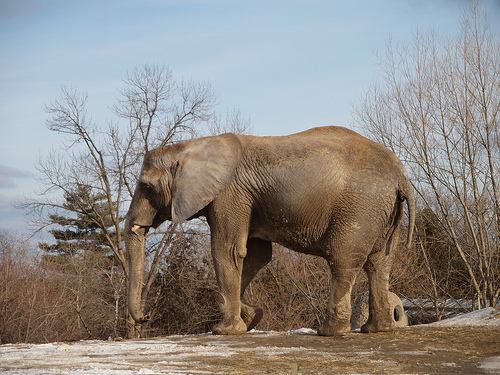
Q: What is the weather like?
A: It is cloudless.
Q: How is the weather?
A: It is cloudless.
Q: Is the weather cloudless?
A: Yes, it is cloudless.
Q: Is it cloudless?
A: Yes, it is cloudless.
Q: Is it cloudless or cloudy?
A: It is cloudless.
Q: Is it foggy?
A: No, it is cloudless.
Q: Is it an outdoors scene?
A: Yes, it is outdoors.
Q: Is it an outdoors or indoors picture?
A: It is outdoors.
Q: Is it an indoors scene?
A: No, it is outdoors.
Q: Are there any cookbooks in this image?
A: No, there are no cookbooks.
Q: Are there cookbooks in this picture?
A: No, there are no cookbooks.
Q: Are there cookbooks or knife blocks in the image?
A: No, there are no cookbooks or knife blocks.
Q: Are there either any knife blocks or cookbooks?
A: No, there are no cookbooks or knife blocks.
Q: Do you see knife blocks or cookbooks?
A: No, there are no cookbooks or knife blocks.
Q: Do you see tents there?
A: No, there are no tents.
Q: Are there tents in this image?
A: No, there are no tents.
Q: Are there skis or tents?
A: No, there are no tents or skis.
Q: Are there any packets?
A: No, there are no packets.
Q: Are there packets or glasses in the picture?
A: No, there are no packets or glasses.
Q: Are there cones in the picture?
A: No, there are no cones.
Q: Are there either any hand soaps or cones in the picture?
A: No, there are no cones or hand soaps.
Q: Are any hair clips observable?
A: No, there are no hair clips.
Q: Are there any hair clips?
A: No, there are no hair clips.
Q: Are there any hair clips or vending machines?
A: No, there are no hair clips or vending machines.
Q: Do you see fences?
A: No, there are no fences.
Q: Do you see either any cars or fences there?
A: No, there are no fences or cars.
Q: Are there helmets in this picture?
A: No, there are no helmets.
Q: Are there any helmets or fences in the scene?
A: No, there are no helmets or fences.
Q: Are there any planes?
A: No, there are no planes.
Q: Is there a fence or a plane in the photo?
A: No, there are no airplanes or fences.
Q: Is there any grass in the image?
A: Yes, there is grass.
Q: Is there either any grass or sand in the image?
A: Yes, there is grass.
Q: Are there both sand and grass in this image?
A: No, there is grass but no sand.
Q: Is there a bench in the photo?
A: No, there are no benches.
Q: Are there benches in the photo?
A: No, there are no benches.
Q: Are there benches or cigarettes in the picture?
A: No, there are no benches or cigarettes.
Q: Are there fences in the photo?
A: No, there are no fences.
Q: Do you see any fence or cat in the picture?
A: No, there are no fences or cats.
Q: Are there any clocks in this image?
A: No, there are no clocks.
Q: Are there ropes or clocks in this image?
A: No, there are no clocks or ropes.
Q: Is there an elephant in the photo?
A: Yes, there is an elephant.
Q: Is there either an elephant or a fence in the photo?
A: Yes, there is an elephant.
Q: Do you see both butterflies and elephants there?
A: No, there is an elephant but no butterflies.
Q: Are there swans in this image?
A: No, there are no swans.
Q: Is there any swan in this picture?
A: No, there are no swans.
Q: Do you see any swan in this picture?
A: No, there are no swans.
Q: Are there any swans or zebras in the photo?
A: No, there are no swans or zebras.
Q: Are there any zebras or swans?
A: No, there are no swans or zebras.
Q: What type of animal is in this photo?
A: The animal is an elephant.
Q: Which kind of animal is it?
A: The animal is an elephant.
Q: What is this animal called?
A: This is an elephant.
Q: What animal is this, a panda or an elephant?
A: This is an elephant.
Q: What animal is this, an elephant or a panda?
A: This is an elephant.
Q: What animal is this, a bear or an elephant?
A: This is an elephant.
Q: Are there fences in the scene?
A: No, there are no fences.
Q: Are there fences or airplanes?
A: No, there are no fences or airplanes.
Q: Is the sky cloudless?
A: Yes, the sky is cloudless.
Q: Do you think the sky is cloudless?
A: Yes, the sky is cloudless.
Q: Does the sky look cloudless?
A: Yes, the sky is cloudless.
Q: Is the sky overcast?
A: No, the sky is cloudless.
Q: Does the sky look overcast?
A: No, the sky is cloudless.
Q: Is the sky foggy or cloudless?
A: The sky is cloudless.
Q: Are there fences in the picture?
A: No, there are no fences.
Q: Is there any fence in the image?
A: No, there are no fences.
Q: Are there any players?
A: No, there are no players.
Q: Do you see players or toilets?
A: No, there are no players or toilets.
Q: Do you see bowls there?
A: No, there are no bowls.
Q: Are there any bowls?
A: No, there are no bowls.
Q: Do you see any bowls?
A: No, there are no bowls.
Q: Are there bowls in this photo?
A: No, there are no bowls.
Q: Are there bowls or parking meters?
A: No, there are no bowls or parking meters.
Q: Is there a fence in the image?
A: No, there are no fences.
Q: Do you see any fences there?
A: No, there are no fences.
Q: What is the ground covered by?
A: The ground is covered by the dirt.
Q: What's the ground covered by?
A: The ground is covered by the dirt.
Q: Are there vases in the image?
A: No, there are no vases.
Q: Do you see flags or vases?
A: No, there are no vases or flags.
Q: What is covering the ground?
A: The dirt is covering the ground.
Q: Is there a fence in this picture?
A: No, there are no fences.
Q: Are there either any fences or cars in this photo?
A: No, there are no fences or cars.